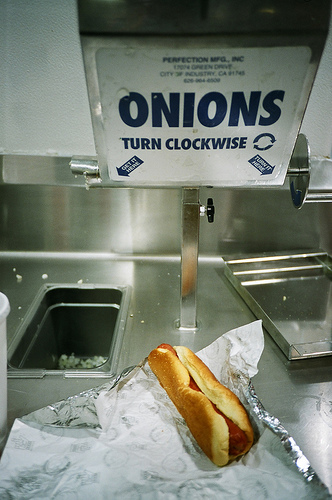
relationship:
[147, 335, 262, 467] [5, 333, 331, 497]
hotdog on counter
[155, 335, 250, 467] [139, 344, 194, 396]
hotdog on bun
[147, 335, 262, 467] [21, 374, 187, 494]
hotdog on paper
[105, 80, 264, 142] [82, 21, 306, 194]
onion machine sign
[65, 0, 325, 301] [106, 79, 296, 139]
machine for onions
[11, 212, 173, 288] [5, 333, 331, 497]
stainless steel counter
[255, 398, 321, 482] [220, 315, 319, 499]
foil sided wrapper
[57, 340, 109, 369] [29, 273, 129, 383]
onions in bin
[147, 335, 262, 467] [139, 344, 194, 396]
hotdog in bun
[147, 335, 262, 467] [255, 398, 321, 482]
hotdog on foil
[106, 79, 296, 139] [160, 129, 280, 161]
onions turn clockwise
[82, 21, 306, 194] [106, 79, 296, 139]
sign says onions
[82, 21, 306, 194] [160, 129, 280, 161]
sign says clockwise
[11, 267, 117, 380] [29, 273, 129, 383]
food in sink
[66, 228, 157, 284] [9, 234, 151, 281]
shining on surface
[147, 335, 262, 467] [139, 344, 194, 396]
hotdog has bun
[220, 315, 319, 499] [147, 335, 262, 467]
wrapper of hotdog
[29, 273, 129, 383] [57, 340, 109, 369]
bucket with onions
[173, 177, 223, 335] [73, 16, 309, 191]
pole holding box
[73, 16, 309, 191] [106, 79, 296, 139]
box for onions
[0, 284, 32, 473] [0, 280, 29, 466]
side of cup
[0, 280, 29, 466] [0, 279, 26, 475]
cup for soda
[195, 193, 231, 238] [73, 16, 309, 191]
dial on box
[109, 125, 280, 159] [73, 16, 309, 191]
directions on box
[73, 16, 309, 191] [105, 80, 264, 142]
box for onion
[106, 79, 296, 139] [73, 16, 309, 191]
onions in box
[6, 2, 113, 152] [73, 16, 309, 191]
wall behind box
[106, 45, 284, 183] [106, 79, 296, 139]
texts says onions